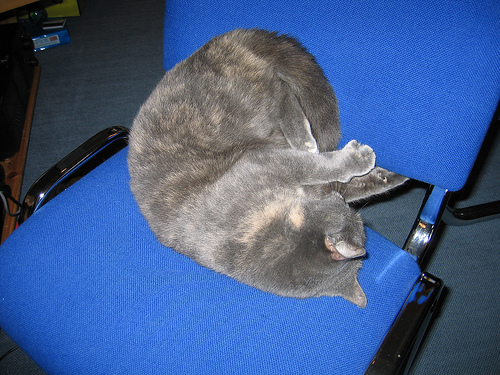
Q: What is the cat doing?
A: Playing on a chair.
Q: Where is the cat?
A: On the chair.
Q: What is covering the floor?
A: Blue carpet.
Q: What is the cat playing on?
A: The chair.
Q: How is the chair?
A: Blue.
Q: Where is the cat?
A: On the chair.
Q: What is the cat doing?
A: Playing.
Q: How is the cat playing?
A: By pawing on the chair's back.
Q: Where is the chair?
A: On the floor.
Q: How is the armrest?
A: Shiny and black.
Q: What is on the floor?
A: A blue object.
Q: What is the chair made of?
A: Blue cloth.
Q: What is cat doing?
A: Playing.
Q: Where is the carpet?
A: On floor.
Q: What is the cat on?
A: Chair.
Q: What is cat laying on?
A: Chair.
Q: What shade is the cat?
A: Gray.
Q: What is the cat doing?
A: Laying.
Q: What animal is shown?
A: Cat.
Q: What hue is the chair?
A: Blue.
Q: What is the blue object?
A: Chair.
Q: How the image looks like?
A: Good.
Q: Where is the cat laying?
A: On blue chair.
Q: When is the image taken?
A: Cat in a chair.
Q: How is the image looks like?
A: Good.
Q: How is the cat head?
A: Down.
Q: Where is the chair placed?
A: On ground.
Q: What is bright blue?
A: The chair.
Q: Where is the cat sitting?
A: On the chair.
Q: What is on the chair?
A: The cat.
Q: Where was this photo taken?
A: Inside on a chair.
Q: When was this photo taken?
A: While the cat was on the chair.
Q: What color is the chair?
A: Blue.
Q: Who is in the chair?
A: A cat.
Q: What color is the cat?
A: Gray.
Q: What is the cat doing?
A: Resting on the chair.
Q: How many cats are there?
A: One.